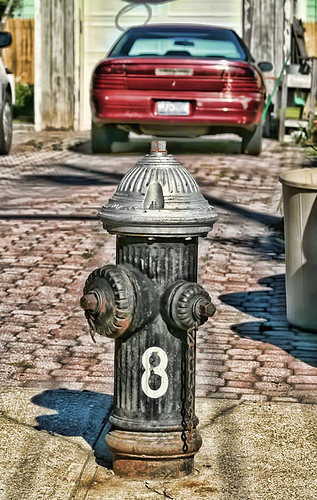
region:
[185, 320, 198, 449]
chain on hydrant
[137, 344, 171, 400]
number 8 on hydrant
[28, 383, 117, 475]
shadow of hydrant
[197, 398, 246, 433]
crack in pavement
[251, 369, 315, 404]
brick paving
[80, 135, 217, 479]
gray and rusty fire hydrant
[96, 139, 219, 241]
domed top of fire hydrant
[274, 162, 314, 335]
trash barrel on brick pavement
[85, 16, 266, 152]
red parked car in front of garage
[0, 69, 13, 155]
wheel of dark gray car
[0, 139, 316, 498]
fire hydrant on sidewalk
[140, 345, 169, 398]
number eight is white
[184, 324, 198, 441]
rusty chain on fire hydrant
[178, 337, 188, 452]
shadow cast by chain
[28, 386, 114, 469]
shadow cast by fire hydrant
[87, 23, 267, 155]
back of red car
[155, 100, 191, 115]
license plate on car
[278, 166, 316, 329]
gray trash can by curb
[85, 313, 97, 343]
broken chain on fire hydrant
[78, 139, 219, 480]
fire hydrant is rusty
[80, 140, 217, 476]
Rusted metal fire extinguisher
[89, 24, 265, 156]
Older red vehicle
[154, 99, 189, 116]
License plate on the back of car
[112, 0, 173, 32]
Shadow from a basketball hoop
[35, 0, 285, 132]
Old wood car garage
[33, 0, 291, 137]
Single vehicle garage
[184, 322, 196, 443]
Rusted metal chain hanging on fire extinguisher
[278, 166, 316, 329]
Tan stained garbage can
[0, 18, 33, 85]
Light brown wood fence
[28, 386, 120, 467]
Shadow of fire extinguisher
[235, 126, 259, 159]
Black wheel on car.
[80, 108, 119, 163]
Black wheel on car.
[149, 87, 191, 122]
White license plate on car.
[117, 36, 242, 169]
Red car parked in driveway.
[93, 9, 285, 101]
White garage door on garage.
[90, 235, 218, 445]
Black fire hydrant in sidewalk.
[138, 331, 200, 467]
White number 8 on fire hydrant.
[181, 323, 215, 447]
Metal chain hanging off of fire hydrant.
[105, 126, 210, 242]
Top of fire hydrant is silver.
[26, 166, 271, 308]
Drive way is made of bricks.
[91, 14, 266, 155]
Car parked on driveway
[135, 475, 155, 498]
Crack in concrete sidewalk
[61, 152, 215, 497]
Fire hydrant on sidewalk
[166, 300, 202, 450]
chain hanging from hydrant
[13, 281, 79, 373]
Stone formed together to make walkway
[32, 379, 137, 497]
Shadow on the pavement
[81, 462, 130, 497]
Stain on the concrete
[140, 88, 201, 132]
License plate on car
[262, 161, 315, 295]
Trash can on side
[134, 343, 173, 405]
Number 8 on the hydrant